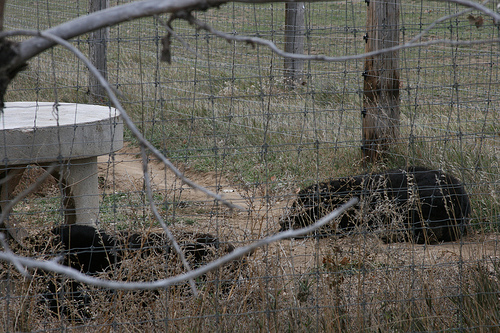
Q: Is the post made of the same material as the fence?
A: No, the post is made of wood and the fence is made of metal.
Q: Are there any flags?
A: No, there are no flags.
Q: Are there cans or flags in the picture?
A: No, there are no flags or cans.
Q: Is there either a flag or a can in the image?
A: No, there are no flags or cans.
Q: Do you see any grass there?
A: Yes, there is grass.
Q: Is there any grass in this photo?
A: Yes, there is grass.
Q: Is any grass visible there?
A: Yes, there is grass.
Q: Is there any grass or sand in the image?
A: Yes, there is grass.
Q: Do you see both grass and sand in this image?
A: No, there is grass but no sand.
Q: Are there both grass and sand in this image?
A: No, there is grass but no sand.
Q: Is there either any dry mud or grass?
A: Yes, there is dry grass.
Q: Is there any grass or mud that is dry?
A: Yes, the grass is dry.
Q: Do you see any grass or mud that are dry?
A: Yes, the grass is dry.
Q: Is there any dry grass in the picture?
A: Yes, there is dry grass.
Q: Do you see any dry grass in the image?
A: Yes, there is dry grass.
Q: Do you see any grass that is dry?
A: Yes, there is dry grass.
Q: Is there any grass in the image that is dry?
A: Yes, there is grass that is dry.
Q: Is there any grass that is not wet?
A: Yes, there is dry grass.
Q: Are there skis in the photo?
A: No, there are no skis.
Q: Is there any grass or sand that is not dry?
A: No, there is grass but it is dry.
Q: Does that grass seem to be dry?
A: Yes, the grass is dry.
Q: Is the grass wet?
A: No, the grass is dry.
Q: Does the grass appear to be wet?
A: No, the grass is dry.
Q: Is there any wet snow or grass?
A: No, there is grass but it is dry.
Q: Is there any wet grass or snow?
A: No, there is grass but it is dry.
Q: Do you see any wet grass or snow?
A: No, there is grass but it is dry.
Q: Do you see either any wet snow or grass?
A: No, there is grass but it is dry.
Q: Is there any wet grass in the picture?
A: No, there is grass but it is dry.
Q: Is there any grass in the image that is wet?
A: No, there is grass but it is dry.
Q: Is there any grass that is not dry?
A: No, there is grass but it is dry.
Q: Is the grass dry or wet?
A: The grass is dry.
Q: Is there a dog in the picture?
A: Yes, there is a dog.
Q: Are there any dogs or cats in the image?
A: Yes, there is a dog.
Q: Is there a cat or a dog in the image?
A: Yes, there is a dog.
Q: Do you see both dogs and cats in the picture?
A: No, there is a dog but no cats.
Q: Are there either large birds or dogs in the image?
A: Yes, there is a large dog.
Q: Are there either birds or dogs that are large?
A: Yes, the dog is large.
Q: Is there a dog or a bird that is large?
A: Yes, the dog is large.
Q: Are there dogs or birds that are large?
A: Yes, the dog is large.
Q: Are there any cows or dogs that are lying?
A: Yes, the dog is lying.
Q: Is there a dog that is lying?
A: Yes, there is a dog that is lying.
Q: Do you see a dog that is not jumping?
A: Yes, there is a dog that is lying .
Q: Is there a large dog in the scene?
A: Yes, there is a large dog.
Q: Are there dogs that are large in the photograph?
A: Yes, there is a large dog.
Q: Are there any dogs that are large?
A: Yes, there is a dog that is large.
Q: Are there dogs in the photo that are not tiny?
A: Yes, there is a large dog.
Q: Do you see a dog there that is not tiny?
A: Yes, there is a large dog.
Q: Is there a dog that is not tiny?
A: Yes, there is a large dog.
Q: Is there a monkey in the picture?
A: No, there are no monkeys.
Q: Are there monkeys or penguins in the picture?
A: No, there are no monkeys or penguins.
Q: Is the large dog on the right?
A: Yes, the dog is on the right of the image.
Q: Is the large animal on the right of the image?
A: Yes, the dog is on the right of the image.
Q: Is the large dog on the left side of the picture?
A: No, the dog is on the right of the image.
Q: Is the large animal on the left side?
A: No, the dog is on the right of the image.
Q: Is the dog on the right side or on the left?
A: The dog is on the right of the image.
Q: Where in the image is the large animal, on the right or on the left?
A: The dog is on the right of the image.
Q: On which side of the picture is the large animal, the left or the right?
A: The dog is on the right of the image.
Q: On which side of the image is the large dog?
A: The dog is on the right of the image.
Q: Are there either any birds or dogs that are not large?
A: No, there is a dog but it is large.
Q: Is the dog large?
A: Yes, the dog is large.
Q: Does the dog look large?
A: Yes, the dog is large.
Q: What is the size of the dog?
A: The dog is large.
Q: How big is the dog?
A: The dog is large.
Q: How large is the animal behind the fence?
A: The dog is large.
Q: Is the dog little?
A: No, the dog is large.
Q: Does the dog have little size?
A: No, the dog is large.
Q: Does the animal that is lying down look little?
A: No, the dog is large.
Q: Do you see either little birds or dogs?
A: No, there is a dog but it is large.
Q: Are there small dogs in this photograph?
A: No, there is a dog but it is large.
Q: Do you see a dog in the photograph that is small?
A: No, there is a dog but it is large.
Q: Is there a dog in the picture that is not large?
A: No, there is a dog but it is large.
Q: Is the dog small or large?
A: The dog is large.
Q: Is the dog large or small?
A: The dog is large.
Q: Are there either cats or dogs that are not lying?
A: No, there is a dog but it is lying.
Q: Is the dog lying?
A: Yes, the dog is lying.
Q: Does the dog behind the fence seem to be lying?
A: Yes, the dog is lying.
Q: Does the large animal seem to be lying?
A: Yes, the dog is lying.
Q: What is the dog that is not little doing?
A: The dog is lying.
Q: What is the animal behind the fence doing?
A: The dog is lying.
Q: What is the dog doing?
A: The dog is lying.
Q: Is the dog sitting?
A: No, the dog is lying.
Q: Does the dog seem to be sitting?
A: No, the dog is lying.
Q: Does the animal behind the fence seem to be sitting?
A: No, the dog is lying.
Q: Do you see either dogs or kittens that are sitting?
A: No, there is a dog but it is lying.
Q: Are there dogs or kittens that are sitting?
A: No, there is a dog but it is lying.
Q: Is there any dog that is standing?
A: No, there is a dog but it is lying.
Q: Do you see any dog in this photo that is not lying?
A: No, there is a dog but it is lying.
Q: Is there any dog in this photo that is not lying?
A: No, there is a dog but it is lying.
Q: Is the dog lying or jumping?
A: The dog is lying.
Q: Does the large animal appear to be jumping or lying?
A: The dog is lying.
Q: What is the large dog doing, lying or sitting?
A: The dog is lying.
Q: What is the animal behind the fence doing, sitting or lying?
A: The dog is lying.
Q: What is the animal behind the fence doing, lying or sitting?
A: The dog is lying.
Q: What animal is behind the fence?
A: The animal is a dog.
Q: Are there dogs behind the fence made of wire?
A: Yes, there is a dog behind the fence.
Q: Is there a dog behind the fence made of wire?
A: Yes, there is a dog behind the fence.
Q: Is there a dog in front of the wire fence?
A: No, the dog is behind the fence.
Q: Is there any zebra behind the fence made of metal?
A: No, there is a dog behind the fence.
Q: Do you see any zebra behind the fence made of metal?
A: No, there is a dog behind the fence.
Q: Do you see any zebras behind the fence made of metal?
A: No, there is a dog behind the fence.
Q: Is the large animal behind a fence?
A: Yes, the dog is behind a fence.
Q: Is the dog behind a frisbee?
A: No, the dog is behind a fence.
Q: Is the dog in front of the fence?
A: No, the dog is behind the fence.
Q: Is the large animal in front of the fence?
A: No, the dog is behind the fence.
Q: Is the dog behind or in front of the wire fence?
A: The dog is behind the fence.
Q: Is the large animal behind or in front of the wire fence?
A: The dog is behind the fence.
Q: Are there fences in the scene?
A: Yes, there is a fence.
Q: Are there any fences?
A: Yes, there is a fence.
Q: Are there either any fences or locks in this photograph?
A: Yes, there is a fence.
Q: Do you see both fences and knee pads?
A: No, there is a fence but no knee pads.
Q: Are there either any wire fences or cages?
A: Yes, there is a wire fence.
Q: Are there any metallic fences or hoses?
A: Yes, there is a metal fence.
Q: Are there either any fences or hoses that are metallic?
A: Yes, the fence is metallic.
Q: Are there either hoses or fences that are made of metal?
A: Yes, the fence is made of metal.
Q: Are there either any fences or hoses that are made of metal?
A: Yes, the fence is made of metal.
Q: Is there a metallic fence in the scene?
A: Yes, there is a metal fence.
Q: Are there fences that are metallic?
A: Yes, there is a fence that is metallic.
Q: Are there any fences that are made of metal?
A: Yes, there is a fence that is made of metal.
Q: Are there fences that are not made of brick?
A: Yes, there is a fence that is made of metal.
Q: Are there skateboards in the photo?
A: No, there are no skateboards.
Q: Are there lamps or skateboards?
A: No, there are no skateboards or lamps.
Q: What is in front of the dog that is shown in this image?
A: The fence is in front of the dog.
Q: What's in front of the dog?
A: The fence is in front of the dog.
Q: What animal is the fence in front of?
A: The fence is in front of the dog.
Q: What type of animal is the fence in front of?
A: The fence is in front of the dog.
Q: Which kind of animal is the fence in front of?
A: The fence is in front of the dog.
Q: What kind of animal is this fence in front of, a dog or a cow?
A: The fence is in front of a dog.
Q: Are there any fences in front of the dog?
A: Yes, there is a fence in front of the dog.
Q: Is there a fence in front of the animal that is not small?
A: Yes, there is a fence in front of the dog.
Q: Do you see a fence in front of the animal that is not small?
A: Yes, there is a fence in front of the dog.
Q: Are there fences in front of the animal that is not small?
A: Yes, there is a fence in front of the dog.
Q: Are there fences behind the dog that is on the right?
A: No, the fence is in front of the dog.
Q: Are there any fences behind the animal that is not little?
A: No, the fence is in front of the dog.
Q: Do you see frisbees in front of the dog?
A: No, there is a fence in front of the dog.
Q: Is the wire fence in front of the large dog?
A: Yes, the fence is in front of the dog.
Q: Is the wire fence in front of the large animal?
A: Yes, the fence is in front of the dog.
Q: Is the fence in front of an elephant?
A: No, the fence is in front of the dog.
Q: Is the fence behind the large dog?
A: No, the fence is in front of the dog.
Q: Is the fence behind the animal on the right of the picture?
A: No, the fence is in front of the dog.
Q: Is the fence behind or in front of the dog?
A: The fence is in front of the dog.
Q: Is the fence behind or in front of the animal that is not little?
A: The fence is in front of the dog.